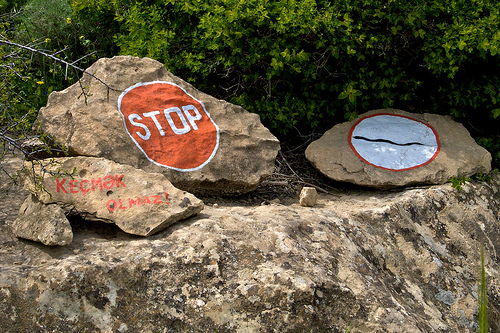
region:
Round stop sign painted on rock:
[100, 78, 219, 175]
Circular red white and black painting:
[349, 112, 440, 177]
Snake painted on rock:
[351, 129, 431, 151]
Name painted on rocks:
[52, 172, 177, 215]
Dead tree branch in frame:
[3, 30, 121, 107]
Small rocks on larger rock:
[16, 55, 493, 253]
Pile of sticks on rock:
[261, 152, 333, 195]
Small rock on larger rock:
[291, 181, 323, 213]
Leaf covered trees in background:
[7, 31, 497, 145]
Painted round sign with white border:
[107, 79, 226, 174]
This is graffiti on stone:
[341, 97, 451, 203]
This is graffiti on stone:
[111, 56, 248, 184]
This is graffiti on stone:
[50, 160, 191, 244]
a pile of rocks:
[1, 11, 493, 322]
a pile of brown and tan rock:
[8, 1, 489, 326]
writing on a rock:
[4, 163, 194, 250]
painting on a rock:
[344, 111, 445, 173]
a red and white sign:
[120, 78, 218, 166]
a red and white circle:
[351, 108, 439, 172]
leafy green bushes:
[241, 35, 498, 122]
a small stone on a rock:
[291, 188, 321, 215]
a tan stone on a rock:
[300, 185, 317, 205]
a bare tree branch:
[8, 38, 119, 115]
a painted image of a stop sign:
[118, 79, 220, 171]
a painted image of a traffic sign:
[348, 112, 440, 167]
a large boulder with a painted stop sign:
[35, 55, 280, 185]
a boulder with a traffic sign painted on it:
[306, 106, 493, 184]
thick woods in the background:
[170, 0, 499, 71]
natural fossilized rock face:
[205, 188, 499, 331]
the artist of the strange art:
[54, 175, 172, 211]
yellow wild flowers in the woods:
[35, 78, 46, 86]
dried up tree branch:
[1, 38, 121, 102]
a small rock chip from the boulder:
[298, 185, 317, 206]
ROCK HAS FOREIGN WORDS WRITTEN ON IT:
[56, 174, 182, 214]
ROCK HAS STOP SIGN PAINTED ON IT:
[110, 65, 225, 187]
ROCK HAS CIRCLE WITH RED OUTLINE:
[348, 111, 445, 186]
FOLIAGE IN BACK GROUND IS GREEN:
[7, 12, 488, 88]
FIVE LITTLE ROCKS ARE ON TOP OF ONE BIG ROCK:
[3, 100, 485, 322]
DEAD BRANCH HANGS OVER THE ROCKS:
[8, 33, 113, 93]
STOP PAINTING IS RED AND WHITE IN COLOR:
[110, 76, 230, 159]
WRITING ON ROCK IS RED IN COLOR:
[54, 174, 174, 216]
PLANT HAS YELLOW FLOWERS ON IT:
[3, 40, 71, 132]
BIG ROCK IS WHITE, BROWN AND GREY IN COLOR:
[76, 223, 496, 298]